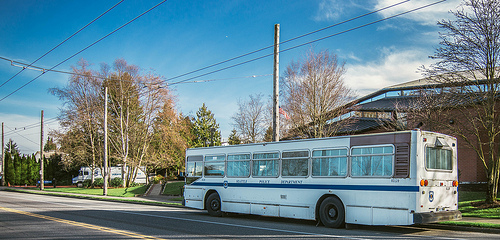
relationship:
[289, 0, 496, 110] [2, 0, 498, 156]
clouds in a sky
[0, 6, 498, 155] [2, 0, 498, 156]
clouds in sky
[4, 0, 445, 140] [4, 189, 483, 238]
power lines above street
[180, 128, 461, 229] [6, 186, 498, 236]
bus on road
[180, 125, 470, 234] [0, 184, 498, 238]
bus on street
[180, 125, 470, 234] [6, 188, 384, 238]
bus on road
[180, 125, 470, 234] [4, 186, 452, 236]
bus on street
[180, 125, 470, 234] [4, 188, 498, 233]
bus on road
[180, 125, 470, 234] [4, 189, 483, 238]
bus on street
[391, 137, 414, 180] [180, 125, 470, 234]
vents are on bus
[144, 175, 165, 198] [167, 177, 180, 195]
sidewalk next to grass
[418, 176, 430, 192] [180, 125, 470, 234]
tail light on bus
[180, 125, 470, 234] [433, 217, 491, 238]
bus parked on curb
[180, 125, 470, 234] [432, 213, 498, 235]
bus parked on curb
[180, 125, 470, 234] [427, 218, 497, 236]
bus parked on curb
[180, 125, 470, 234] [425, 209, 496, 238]
bus parked on curb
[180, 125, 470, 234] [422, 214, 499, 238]
bus parked on curb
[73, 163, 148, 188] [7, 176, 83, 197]
truck parked in driveway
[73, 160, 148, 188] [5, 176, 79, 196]
truck parked in driveway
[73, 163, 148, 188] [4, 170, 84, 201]
truck parked in driveway